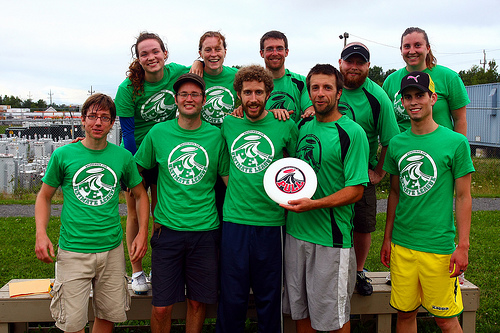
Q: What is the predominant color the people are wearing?
A: Green.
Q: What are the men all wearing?
A: Green t-shirts.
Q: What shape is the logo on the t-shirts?
A: Circles.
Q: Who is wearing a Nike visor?
A: The bald guy in the back.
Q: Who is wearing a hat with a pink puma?
A: The guy on the bottom right.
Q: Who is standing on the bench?
A: The people in the back row.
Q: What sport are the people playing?
A: Frisbee.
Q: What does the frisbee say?
A: Pull.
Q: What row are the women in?
A: In the back row.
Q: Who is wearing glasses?
A: The two guys on the bottom left.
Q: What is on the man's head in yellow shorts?
A: A cap.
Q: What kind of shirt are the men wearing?
A: A green shirt.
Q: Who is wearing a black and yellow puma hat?
A: Man in yellow shorts.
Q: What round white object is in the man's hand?
A: A frisbee.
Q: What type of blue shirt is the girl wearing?
A: Long sleeved shirt.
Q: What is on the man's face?
A: Eyeglasses.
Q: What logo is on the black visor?
A: Nike.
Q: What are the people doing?
A: Posing for picture.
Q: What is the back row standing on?
A: A bench.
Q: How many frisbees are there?
A: One.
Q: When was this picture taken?
A: Daytime.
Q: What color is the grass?
A: Green.